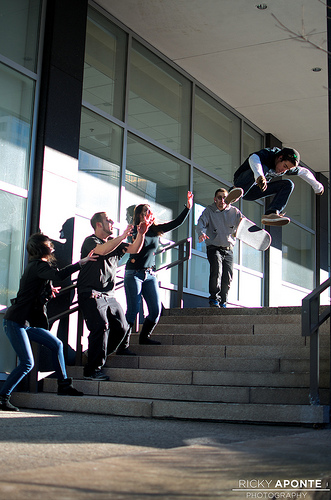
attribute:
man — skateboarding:
[204, 186, 236, 307]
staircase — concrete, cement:
[148, 306, 310, 419]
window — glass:
[131, 39, 194, 162]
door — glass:
[291, 198, 308, 302]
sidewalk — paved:
[11, 418, 323, 499]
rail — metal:
[172, 242, 198, 259]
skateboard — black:
[239, 220, 272, 252]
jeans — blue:
[8, 326, 33, 364]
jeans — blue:
[125, 274, 161, 321]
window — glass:
[3, 66, 30, 189]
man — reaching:
[83, 213, 133, 383]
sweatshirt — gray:
[207, 211, 234, 246]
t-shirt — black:
[261, 153, 275, 167]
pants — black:
[211, 255, 231, 297]